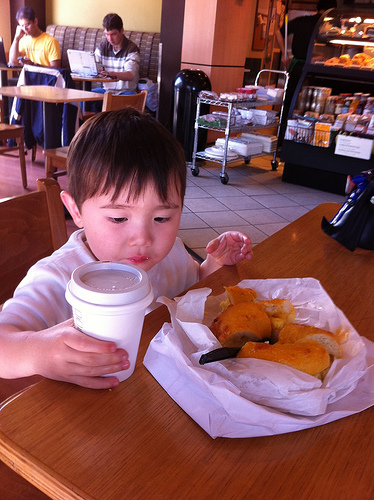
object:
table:
[71, 74, 120, 87]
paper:
[187, 267, 361, 397]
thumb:
[203, 238, 216, 259]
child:
[3, 98, 254, 390]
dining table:
[1, 196, 371, 499]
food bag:
[142, 278, 372, 443]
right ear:
[54, 188, 84, 228]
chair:
[1, 174, 68, 305]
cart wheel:
[215, 170, 232, 189]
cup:
[65, 256, 159, 397]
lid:
[64, 262, 153, 314]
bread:
[205, 278, 332, 379]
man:
[79, 17, 139, 98]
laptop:
[0, 39, 25, 71]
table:
[1, 64, 23, 87]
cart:
[189, 64, 285, 190]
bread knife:
[198, 346, 239, 367]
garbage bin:
[172, 60, 211, 165]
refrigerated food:
[282, 18, 372, 158]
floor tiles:
[184, 184, 280, 229]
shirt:
[281, 15, 320, 60]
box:
[211, 133, 263, 158]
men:
[4, 11, 140, 96]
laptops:
[64, 45, 99, 77]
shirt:
[11, 33, 61, 72]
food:
[200, 80, 279, 130]